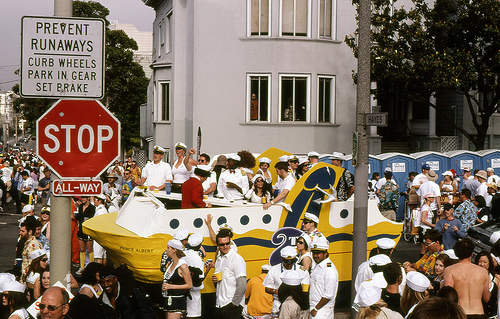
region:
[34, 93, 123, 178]
Stop sign mounted on pole.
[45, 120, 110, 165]
The word stop on the stop sign.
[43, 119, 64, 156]
The letter S on the stop sign.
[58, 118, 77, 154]
The letter T on the stop sign.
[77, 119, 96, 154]
The letter O on the stop sign.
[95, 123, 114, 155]
The letter P on the stop sign.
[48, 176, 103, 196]
The red and white All- Way sign below the stop sign.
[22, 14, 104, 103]
Black and white street sign above the stop sign.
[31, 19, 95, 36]
The word prevent on the white and black sign.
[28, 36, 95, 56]
The word runaways on the black and white sign.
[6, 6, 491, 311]
people at a parade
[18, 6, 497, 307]
people riding in a parade float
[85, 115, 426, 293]
boat float at a parade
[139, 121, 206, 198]
boat captain at a parade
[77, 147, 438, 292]
blue white and yellow cruise ship float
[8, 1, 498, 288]
gray building in the background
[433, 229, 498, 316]
topless man at a parade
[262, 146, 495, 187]
blue outhouses in the background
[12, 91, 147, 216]
stop sign attached to a pole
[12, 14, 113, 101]
white traffic directive signage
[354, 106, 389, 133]
street sign on a pole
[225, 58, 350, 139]
windows on a building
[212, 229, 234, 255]
glasses on a persons face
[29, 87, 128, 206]
red sign on a pole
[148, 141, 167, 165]
white hat on a persons head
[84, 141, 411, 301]
float with people in a parade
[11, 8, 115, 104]
white sign with black letters on a pole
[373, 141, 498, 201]
portable bathrooms behind a crowd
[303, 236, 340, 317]
person with a white shirt and pants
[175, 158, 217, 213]
person with a red shirt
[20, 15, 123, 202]
street signs sitting on the pole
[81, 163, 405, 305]
a float made to look like a boat.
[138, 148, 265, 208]
people dressed up in sailor outfits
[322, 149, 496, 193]
a line of portapotties by the side of the road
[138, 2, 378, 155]
a building sitting on the side of the road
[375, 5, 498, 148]
a tree sitting in front of a building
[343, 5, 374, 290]
a tall pole sitting next to the pole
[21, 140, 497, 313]
a large crowd of people standing around for a parade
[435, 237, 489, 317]
a topless man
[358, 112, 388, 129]
a street sign on a pole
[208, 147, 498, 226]
The port-o-potties are line up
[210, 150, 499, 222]
The port-o-potties are blue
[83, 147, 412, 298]
The ship float is yellow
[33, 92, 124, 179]
The stop sign is red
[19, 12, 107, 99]
The sign above the stop sign is square and white with black letters printed on it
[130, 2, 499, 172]
The building on the opposite side of the street is white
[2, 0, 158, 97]
The sky is grey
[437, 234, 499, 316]
One of the men is not wearing a shirt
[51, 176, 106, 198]
A small red sign beneath the stop sign is red with white lettering that reads ALL-WAY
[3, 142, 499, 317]
There is a large crowd of people in the street